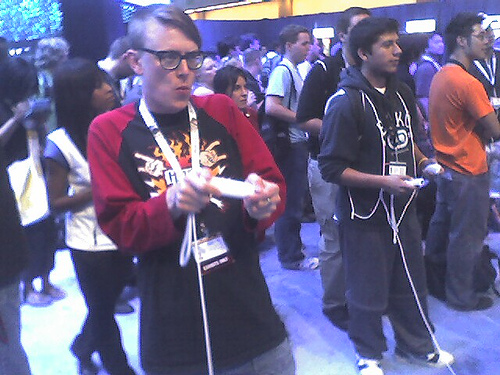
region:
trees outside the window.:
[7, 5, 44, 30]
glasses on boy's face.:
[159, 50, 196, 69]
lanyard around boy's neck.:
[147, 122, 179, 167]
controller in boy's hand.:
[213, 185, 252, 197]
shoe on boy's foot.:
[355, 354, 378, 374]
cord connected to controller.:
[196, 280, 212, 357]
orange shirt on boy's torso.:
[443, 79, 461, 139]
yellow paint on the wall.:
[233, 7, 273, 12]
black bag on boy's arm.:
[262, 117, 284, 152]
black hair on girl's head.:
[67, 68, 81, 113]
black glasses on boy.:
[160, 47, 188, 66]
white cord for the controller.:
[192, 298, 222, 355]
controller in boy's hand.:
[217, 174, 248, 196]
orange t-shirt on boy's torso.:
[442, 75, 458, 137]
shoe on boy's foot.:
[353, 347, 368, 374]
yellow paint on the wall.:
[232, 12, 272, 19]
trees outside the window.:
[15, 7, 47, 22]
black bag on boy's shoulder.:
[265, 121, 283, 147]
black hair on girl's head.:
[68, 66, 86, 97]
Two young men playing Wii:
[97, 3, 444, 372]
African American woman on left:
[58, 59, 123, 372]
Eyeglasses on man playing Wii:
[123, 44, 210, 70]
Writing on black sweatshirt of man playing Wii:
[369, 103, 421, 167]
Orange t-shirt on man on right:
[426, 58, 496, 174]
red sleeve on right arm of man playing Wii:
[89, 101, 173, 252]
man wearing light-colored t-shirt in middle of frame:
[266, 22, 315, 276]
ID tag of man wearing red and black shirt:
[183, 234, 239, 274]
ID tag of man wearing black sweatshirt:
[383, 159, 410, 177]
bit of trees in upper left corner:
[4, 5, 50, 31]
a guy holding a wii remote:
[64, 9, 319, 348]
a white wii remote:
[168, 153, 314, 260]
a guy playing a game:
[72, 14, 328, 289]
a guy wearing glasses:
[87, 3, 244, 130]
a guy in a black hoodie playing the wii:
[302, 12, 487, 267]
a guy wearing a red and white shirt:
[75, 23, 315, 307]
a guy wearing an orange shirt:
[410, 16, 493, 207]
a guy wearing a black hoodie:
[301, 18, 478, 281]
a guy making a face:
[36, 25, 361, 337]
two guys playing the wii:
[85, 10, 497, 310]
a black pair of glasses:
[128, 40, 208, 72]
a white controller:
[196, 175, 264, 200]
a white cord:
[182, 214, 221, 373]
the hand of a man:
[168, 162, 223, 219]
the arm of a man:
[311, 97, 382, 199]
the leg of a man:
[339, 206, 391, 363]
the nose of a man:
[174, 57, 190, 80]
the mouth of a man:
[165, 80, 197, 93]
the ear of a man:
[123, 46, 144, 81]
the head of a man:
[118, 2, 203, 120]